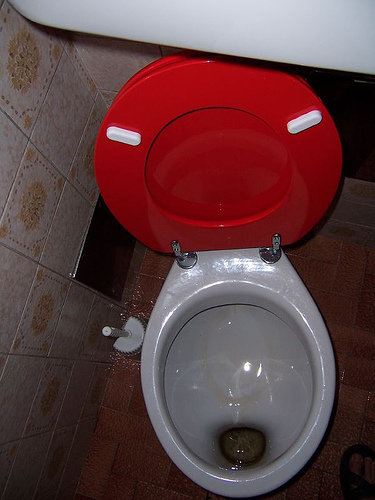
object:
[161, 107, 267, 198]
red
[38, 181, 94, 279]
ceramic tile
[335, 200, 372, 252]
floor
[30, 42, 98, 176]
tile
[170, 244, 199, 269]
hinge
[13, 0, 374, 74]
top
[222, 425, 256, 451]
water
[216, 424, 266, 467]
hole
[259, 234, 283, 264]
hinge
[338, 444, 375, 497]
sandals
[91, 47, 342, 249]
lid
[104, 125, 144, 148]
white stopper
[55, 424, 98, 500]
tile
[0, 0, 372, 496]
restroom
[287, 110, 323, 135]
stopper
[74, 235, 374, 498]
tiles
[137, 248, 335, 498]
bowl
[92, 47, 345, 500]
toilet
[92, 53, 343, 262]
toilet seat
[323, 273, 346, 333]
floor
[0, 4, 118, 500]
wall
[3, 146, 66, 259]
brown tile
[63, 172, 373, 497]
ground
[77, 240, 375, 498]
linoleum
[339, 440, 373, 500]
floor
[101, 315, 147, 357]
brush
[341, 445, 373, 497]
foot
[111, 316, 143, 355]
holder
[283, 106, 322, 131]
piece